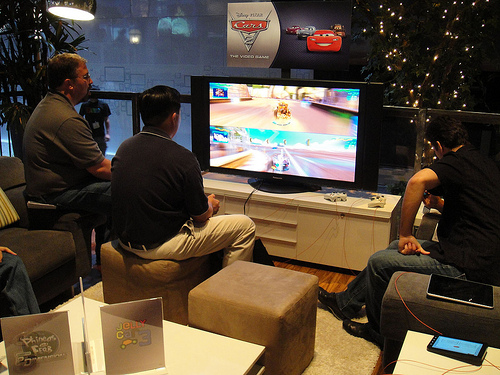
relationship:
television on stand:
[182, 68, 381, 198] [195, 165, 438, 280]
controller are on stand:
[322, 189, 349, 202] [145, 146, 410, 303]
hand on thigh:
[391, 228, 430, 262] [326, 225, 465, 320]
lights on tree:
[378, 0, 493, 155] [341, 4, 483, 135]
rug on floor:
[86, 249, 373, 372] [4, 156, 484, 361]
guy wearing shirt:
[108, 84, 258, 274] [107, 131, 216, 247]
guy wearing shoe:
[312, 103, 500, 344] [311, 269, 385, 348]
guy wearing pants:
[108, 84, 258, 274] [95, 216, 268, 293]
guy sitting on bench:
[108, 84, 258, 274] [97, 245, 239, 351]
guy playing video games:
[108, 84, 258, 274] [179, 79, 360, 223]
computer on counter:
[427, 329, 486, 360] [401, 319, 472, 370]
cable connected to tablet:
[382, 267, 437, 334] [425, 330, 485, 372]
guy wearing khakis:
[108, 84, 258, 274] [162, 199, 275, 289]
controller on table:
[322, 189, 349, 202] [233, 167, 447, 221]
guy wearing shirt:
[108, 84, 258, 274] [104, 139, 207, 237]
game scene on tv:
[194, 76, 375, 215] [173, 62, 381, 207]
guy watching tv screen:
[26, 44, 106, 146] [175, 69, 373, 212]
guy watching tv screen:
[99, 77, 208, 182] [175, 69, 373, 212]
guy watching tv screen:
[407, 103, 494, 214] [175, 69, 373, 212]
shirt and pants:
[107, 131, 216, 247] [113, 204, 319, 300]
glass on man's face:
[72, 71, 86, 84] [72, 60, 99, 100]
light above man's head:
[40, 2, 99, 35] [45, 36, 96, 85]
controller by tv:
[322, 180, 358, 219] [186, 68, 382, 193]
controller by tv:
[363, 188, 393, 213] [186, 68, 382, 193]